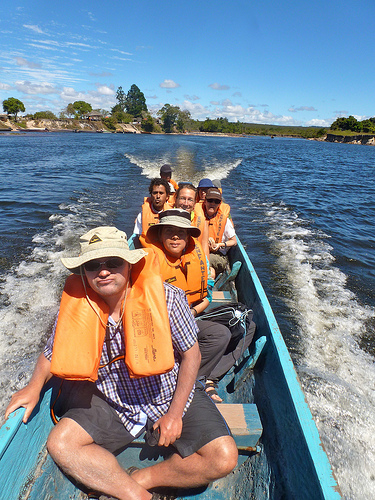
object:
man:
[5, 221, 237, 496]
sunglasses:
[86, 260, 124, 274]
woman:
[145, 205, 256, 378]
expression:
[164, 230, 190, 253]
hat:
[59, 225, 150, 269]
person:
[174, 180, 199, 213]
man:
[133, 177, 171, 225]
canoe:
[1, 133, 375, 449]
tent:
[84, 108, 106, 123]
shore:
[2, 118, 148, 133]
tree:
[1, 94, 26, 123]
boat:
[0, 168, 343, 499]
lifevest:
[48, 270, 177, 379]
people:
[29, 166, 237, 465]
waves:
[118, 140, 246, 176]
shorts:
[61, 393, 232, 457]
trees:
[3, 90, 373, 133]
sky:
[1, 0, 371, 117]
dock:
[14, 127, 52, 134]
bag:
[204, 312, 248, 351]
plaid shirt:
[44, 294, 195, 432]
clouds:
[5, 15, 366, 120]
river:
[0, 129, 374, 301]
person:
[159, 163, 180, 191]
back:
[145, 157, 241, 229]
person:
[197, 188, 235, 255]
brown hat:
[204, 187, 222, 206]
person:
[197, 175, 220, 200]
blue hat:
[200, 179, 212, 189]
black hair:
[150, 179, 169, 193]